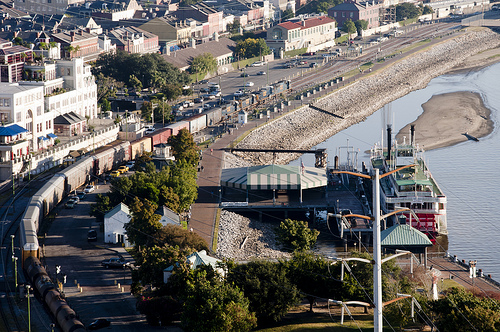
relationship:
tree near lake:
[289, 252, 329, 315] [283, 60, 498, 285]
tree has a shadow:
[289, 252, 329, 315] [298, 311, 353, 321]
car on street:
[258, 70, 266, 78] [179, 63, 312, 106]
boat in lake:
[374, 126, 449, 236] [283, 60, 498, 285]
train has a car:
[209, 81, 287, 126] [89, 138, 129, 175]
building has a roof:
[269, 22, 341, 51] [274, 7, 337, 34]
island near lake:
[388, 84, 492, 156] [283, 60, 498, 285]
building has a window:
[6, 73, 101, 132] [55, 102, 61, 108]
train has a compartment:
[209, 81, 287, 126] [65, 156, 98, 189]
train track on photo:
[304, 60, 363, 85] [0, 1, 495, 327]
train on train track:
[209, 81, 287, 126] [304, 60, 363, 85]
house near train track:
[177, 9, 228, 41] [304, 60, 363, 85]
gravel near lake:
[271, 109, 316, 150] [283, 60, 498, 285]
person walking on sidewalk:
[209, 148, 216, 158] [193, 155, 219, 236]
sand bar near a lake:
[310, 102, 350, 124] [445, 153, 497, 261]